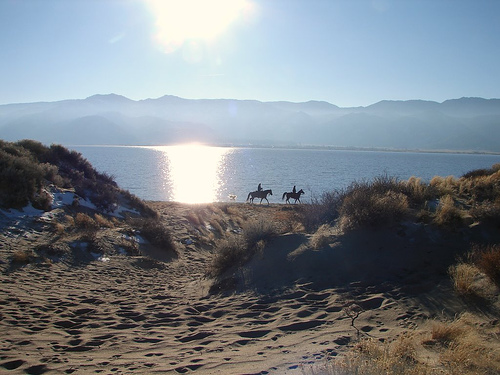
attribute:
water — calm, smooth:
[22, 135, 499, 210]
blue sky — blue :
[264, 2, 499, 86]